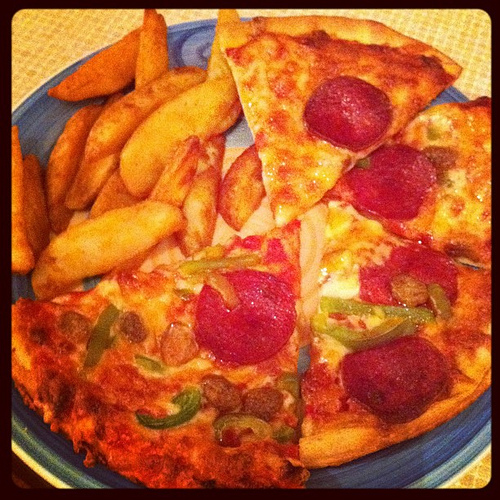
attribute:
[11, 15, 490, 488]
plate — round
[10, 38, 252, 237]
fries — brown, crispy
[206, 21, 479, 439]
pizza — topped, cheesy